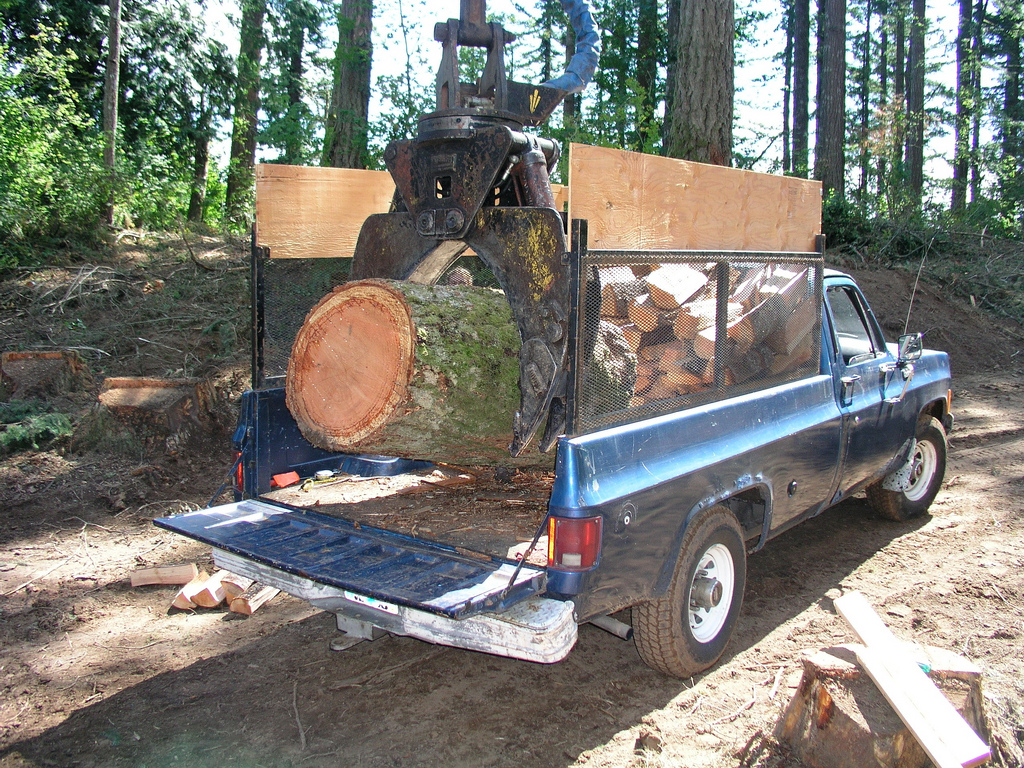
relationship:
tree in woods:
[942, 0, 985, 216] [1, 4, 1000, 442]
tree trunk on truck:
[285, 278, 536, 468] [171, 191, 947, 651]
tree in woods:
[942, 4, 999, 217] [4, 4, 998, 324]